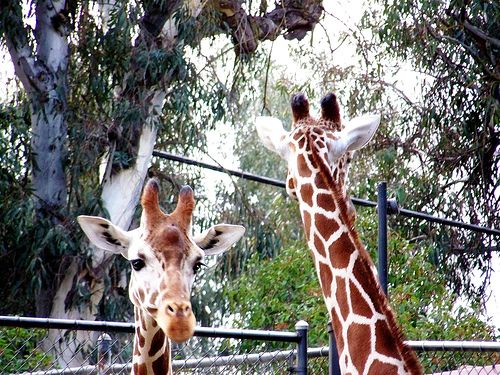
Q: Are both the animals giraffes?
A: Yes, all the animals are giraffes.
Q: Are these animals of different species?
A: No, all the animals are giraffes.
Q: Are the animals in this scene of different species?
A: No, all the animals are giraffes.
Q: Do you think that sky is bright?
A: Yes, the sky is bright.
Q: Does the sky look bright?
A: Yes, the sky is bright.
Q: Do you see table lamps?
A: No, there are no table lamps.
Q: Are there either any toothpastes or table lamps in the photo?
A: No, there are no table lamps or toothpastes.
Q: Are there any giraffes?
A: Yes, there is a giraffe.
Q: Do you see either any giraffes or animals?
A: Yes, there is a giraffe.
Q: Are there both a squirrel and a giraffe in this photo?
A: No, there is a giraffe but no squirrels.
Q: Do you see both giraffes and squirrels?
A: No, there is a giraffe but no squirrels.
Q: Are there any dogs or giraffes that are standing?
A: Yes, the giraffe is standing.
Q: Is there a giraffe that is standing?
A: Yes, there is a giraffe that is standing.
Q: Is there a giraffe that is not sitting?
A: Yes, there is a giraffe that is standing.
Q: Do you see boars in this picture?
A: No, there are no boars.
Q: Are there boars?
A: No, there are no boars.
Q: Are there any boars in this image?
A: No, there are no boars.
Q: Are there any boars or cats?
A: No, there are no boars or cats.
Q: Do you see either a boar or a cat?
A: No, there are no boars or cats.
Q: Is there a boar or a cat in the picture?
A: No, there are no boars or cats.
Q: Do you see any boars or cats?
A: No, there are no boars or cats.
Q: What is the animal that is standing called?
A: The animal is a giraffe.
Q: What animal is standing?
A: The animal is a giraffe.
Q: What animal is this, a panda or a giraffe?
A: This is a giraffe.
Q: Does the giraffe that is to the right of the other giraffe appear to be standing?
A: Yes, the giraffe is standing.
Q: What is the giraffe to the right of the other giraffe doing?
A: The giraffe is standing.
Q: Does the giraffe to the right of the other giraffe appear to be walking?
A: No, the giraffe is standing.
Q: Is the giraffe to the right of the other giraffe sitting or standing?
A: The giraffe is standing.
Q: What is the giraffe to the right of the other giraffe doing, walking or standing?
A: The giraffe is standing.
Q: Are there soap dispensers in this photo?
A: No, there are no soap dispensers.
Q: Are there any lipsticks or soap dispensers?
A: No, there are no soap dispensers or lipsticks.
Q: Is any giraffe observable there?
A: Yes, there is a giraffe.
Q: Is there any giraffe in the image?
A: Yes, there is a giraffe.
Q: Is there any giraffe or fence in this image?
A: Yes, there is a giraffe.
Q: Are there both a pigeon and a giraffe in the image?
A: No, there is a giraffe but no pigeons.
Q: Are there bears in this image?
A: No, there are no bears.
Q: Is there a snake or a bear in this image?
A: No, there are no bears or snakes.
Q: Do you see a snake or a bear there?
A: No, there are no bears or snakes.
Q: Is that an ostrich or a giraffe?
A: That is a giraffe.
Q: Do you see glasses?
A: No, there are no glasses.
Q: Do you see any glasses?
A: No, there are no glasses.